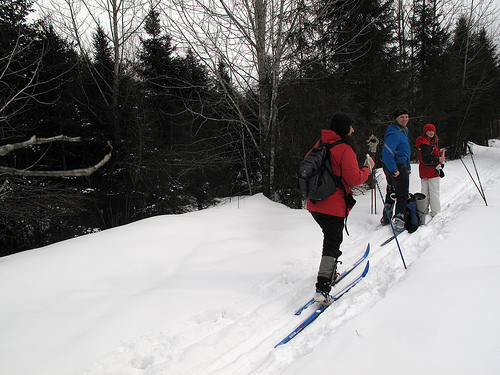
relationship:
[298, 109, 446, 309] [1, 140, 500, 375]
people are on snow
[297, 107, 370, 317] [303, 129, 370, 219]
woman wearing a jacket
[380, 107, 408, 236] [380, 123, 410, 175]
man wearing a jacket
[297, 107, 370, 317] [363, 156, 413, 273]
woman holding ski pole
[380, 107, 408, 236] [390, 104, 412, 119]
man wearing a hat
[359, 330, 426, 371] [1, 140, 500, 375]
patch of snow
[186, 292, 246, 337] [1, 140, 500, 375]
patch of snow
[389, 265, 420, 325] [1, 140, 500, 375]
patch of snow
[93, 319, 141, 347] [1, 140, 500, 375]
patch of snow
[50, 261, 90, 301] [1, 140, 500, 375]
patch of snow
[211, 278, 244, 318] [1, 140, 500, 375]
patch of snow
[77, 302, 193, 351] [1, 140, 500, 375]
patch of snow